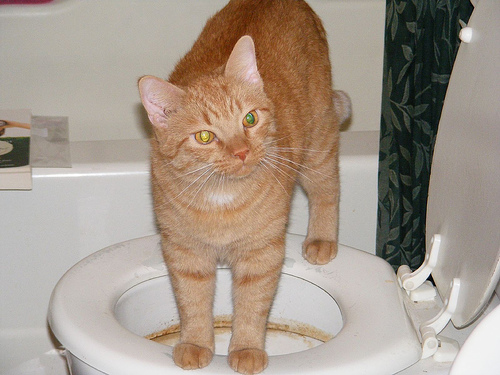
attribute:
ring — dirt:
[140, 313, 334, 353]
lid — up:
[415, 3, 499, 324]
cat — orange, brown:
[132, 0, 346, 372]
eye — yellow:
[188, 124, 217, 147]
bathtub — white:
[5, 0, 383, 371]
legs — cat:
[155, 230, 279, 370]